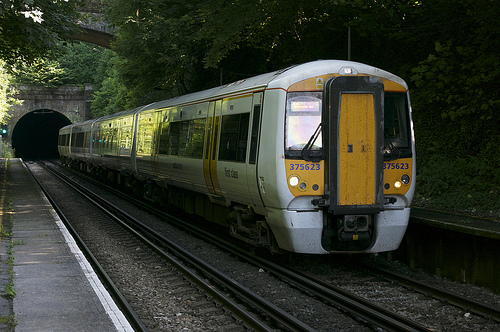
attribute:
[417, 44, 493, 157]
tree — green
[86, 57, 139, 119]
tree — green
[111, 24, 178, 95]
tree — green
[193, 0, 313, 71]
tree — green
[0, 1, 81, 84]
tree — green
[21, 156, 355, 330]
track — brown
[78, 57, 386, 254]
train — yellow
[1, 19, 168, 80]
plants — green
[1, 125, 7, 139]
light — green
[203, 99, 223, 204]
door — yellow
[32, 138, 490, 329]
railway — metal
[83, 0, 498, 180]
trees — green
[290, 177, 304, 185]
headlight — on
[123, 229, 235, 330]
train track — empty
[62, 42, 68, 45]
leaf — green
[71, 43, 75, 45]
leaf — green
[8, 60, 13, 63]
leaf — green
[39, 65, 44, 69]
leaf — green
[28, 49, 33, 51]
leaf — green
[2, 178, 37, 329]
grass — green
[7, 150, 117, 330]
platform — grey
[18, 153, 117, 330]
lines — white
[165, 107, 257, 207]
doors — close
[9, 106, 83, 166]
tunnel — black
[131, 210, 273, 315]
tracks — parrallel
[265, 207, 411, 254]
bumper — white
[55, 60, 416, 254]
train — yellow, white, gray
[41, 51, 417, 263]
train — long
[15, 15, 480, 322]
picture — daytime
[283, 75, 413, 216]
front — train front, yellow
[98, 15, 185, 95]
tree — green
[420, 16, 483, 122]
tree — green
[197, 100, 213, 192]
door — close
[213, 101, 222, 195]
door — close